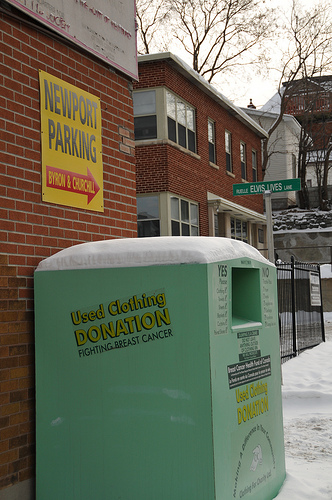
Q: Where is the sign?
A: On a brick building.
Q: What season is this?
A: Winter.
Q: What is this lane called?
A: Elvis Lives.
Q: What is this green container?
A: Donation box.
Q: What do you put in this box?
A: Used clothing.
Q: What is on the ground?
A: Snow.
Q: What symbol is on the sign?
A: Arrow.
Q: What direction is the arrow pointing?
A: Right.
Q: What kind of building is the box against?
A: Brick.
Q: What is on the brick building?
A: Yellow sign.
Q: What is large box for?
A: Clothing donation.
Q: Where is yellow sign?
A: Brick building.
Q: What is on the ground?
A: Snow.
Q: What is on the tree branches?
A: Nothing.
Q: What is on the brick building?
A: Windows.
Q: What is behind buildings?
A: Trees.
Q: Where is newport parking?
A: To the right.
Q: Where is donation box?
A: On street.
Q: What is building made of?
A: Brick.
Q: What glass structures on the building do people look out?
A: Windows.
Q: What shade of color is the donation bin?
A: Green.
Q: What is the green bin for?
A: Used clothing.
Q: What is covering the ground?
A: Snow.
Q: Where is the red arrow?
A: On the newport parking sign.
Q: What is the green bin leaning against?
A: A brick wall.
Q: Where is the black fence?
A: By the street sign.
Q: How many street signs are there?
A: One.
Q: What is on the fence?
A: A sign.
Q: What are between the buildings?
A: Trees.